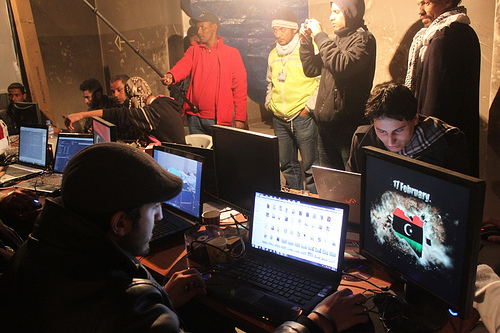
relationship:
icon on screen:
[264, 202, 271, 210] [224, 183, 321, 270]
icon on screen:
[263, 211, 271, 219] [224, 183, 321, 270]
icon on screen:
[282, 214, 291, 222] [224, 183, 321, 270]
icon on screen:
[304, 209, 311, 219] [224, 183, 321, 270]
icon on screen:
[316, 234, 324, 241] [224, 183, 321, 270]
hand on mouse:
[302, 283, 369, 331] [354, 290, 376, 315]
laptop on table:
[201, 186, 353, 324] [190, 251, 406, 331]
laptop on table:
[206, 188, 350, 324] [191, 236, 394, 330]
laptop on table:
[15, 122, 95, 206] [14, 121, 474, 328]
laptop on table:
[5, 112, 52, 189] [0, 132, 499, 332]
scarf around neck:
[399, 4, 474, 93] [416, 8, 471, 32]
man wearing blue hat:
[160, 9, 247, 134] [183, 3, 220, 25]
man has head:
[0, 141, 370, 332] [61, 143, 183, 261]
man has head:
[345, 81, 469, 176] [364, 81, 420, 153]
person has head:
[100, 69, 147, 144] [104, 63, 130, 103]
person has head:
[75, 74, 113, 133] [80, 74, 106, 109]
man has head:
[263, 9, 323, 194] [268, 8, 303, 45]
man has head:
[160, 9, 247, 134] [187, 10, 222, 44]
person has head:
[393, 0, 498, 174] [409, 0, 477, 29]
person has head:
[4, 79, 54, 129] [2, 77, 34, 111]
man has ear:
[160, 9, 247, 134] [207, 22, 222, 34]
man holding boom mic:
[155, 8, 250, 133] [79, 0, 199, 110]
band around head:
[268, 19, 300, 29] [60, 119, 187, 256]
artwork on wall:
[188, 1, 311, 88] [96, 4, 484, 192]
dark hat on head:
[57, 125, 198, 224] [59, 136, 187, 261]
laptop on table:
[206, 188, 350, 324] [1, 164, 454, 331]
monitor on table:
[357, 146, 486, 321] [1, 164, 454, 331]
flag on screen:
[386, 210, 417, 248] [346, 137, 476, 290]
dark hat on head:
[58, 141, 183, 214] [88, 196, 165, 261]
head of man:
[88, 196, 165, 261] [4, 147, 206, 331]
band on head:
[271, 20, 300, 29] [272, 10, 300, 46]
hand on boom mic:
[160, 69, 174, 88] [79, 0, 199, 110]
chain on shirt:
[273, 39, 292, 81] [260, 39, 326, 119]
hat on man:
[264, 9, 298, 33] [263, 9, 323, 194]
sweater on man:
[308, 46, 395, 123] [239, 17, 341, 142]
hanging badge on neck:
[271, 55, 293, 85] [270, 37, 302, 53]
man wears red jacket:
[160, 9, 247, 134] [162, 42, 247, 119]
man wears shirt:
[263, 9, 323, 194] [259, 42, 321, 114]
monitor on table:
[352, 136, 484, 316] [162, 215, 492, 332]